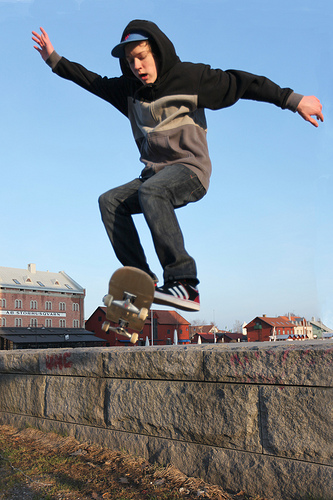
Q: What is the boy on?
A: Skateboard.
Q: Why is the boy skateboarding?
A: Recreation.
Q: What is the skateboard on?
A: Wall.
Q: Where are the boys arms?
A: Extended.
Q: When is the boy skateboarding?
A: Daytime.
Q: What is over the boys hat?
A: Hood.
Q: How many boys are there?
A: One.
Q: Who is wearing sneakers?
A: THe boy.